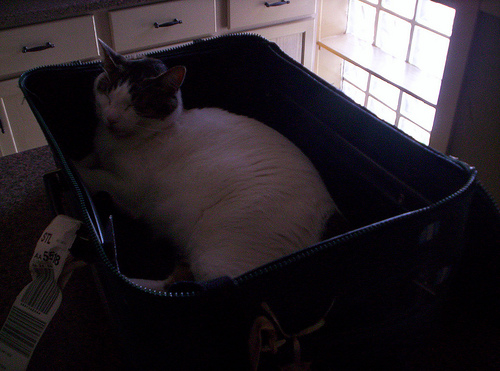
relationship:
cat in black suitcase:
[90, 36, 341, 291] [17, 32, 499, 368]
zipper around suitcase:
[434, 168, 479, 206] [9, 27, 490, 301]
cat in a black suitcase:
[90, 36, 341, 291] [17, 32, 499, 368]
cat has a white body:
[90, 36, 341, 291] [156, 151, 280, 291]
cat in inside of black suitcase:
[90, 36, 341, 291] [17, 32, 499, 368]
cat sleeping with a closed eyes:
[90, 36, 341, 291] [107, 70, 201, 159]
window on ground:
[331, 8, 453, 138] [189, 54, 463, 301]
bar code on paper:
[13, 257, 72, 318] [4, 209, 93, 369]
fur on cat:
[132, 114, 334, 276] [90, 36, 341, 291]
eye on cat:
[98, 84, 109, 102] [90, 36, 341, 291]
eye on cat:
[124, 99, 138, 112] [90, 36, 341, 291]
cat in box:
[61, 47, 346, 270] [18, 29, 474, 366]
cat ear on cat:
[93, 34, 122, 67] [58, 29, 384, 294]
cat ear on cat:
[155, 56, 197, 92] [58, 29, 384, 294]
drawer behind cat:
[3, 7, 99, 84] [63, 32, 349, 297]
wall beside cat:
[435, 8, 498, 193] [90, 36, 341, 291]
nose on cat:
[103, 112, 120, 123] [90, 36, 341, 291]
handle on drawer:
[22, 38, 54, 55] [2, 17, 99, 71]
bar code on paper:
[20, 257, 71, 325] [0, 210, 88, 370]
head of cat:
[94, 39, 181, 121] [85, 38, 321, 294]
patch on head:
[90, 47, 183, 121] [94, 39, 181, 121]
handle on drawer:
[22, 38, 54, 55] [20, 18, 133, 97]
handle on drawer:
[153, 17, 181, 28] [107, 0, 216, 55]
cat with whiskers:
[90, 36, 341, 291] [68, 94, 173, 147]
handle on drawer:
[22, 38, 54, 55] [0, 13, 102, 79]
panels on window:
[343, 0, 379, 46] [331, 2, 451, 147]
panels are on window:
[317, 0, 465, 170] [361, 21, 498, 103]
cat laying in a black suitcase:
[90, 36, 341, 291] [17, 32, 499, 368]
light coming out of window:
[382, 22, 401, 49] [344, 1, 439, 63]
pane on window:
[326, 13, 438, 93] [293, 0, 467, 170]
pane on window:
[373, 14, 410, 58] [309, 0, 470, 170]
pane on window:
[352, 67, 454, 137] [314, 0, 459, 163]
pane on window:
[340, 58, 375, 98] [321, 11, 449, 142]